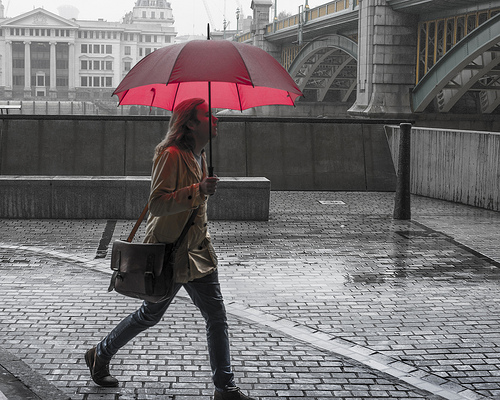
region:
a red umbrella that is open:
[121, 25, 296, 103]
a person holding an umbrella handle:
[195, 78, 220, 195]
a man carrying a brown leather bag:
[105, 100, 241, 300]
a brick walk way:
[307, 244, 426, 316]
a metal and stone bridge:
[220, 10, 498, 105]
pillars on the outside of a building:
[17, 40, 59, 95]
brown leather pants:
[75, 275, 251, 369]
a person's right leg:
[105, 295, 166, 341]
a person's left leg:
[194, 288, 245, 375]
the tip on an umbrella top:
[202, 20, 217, 44]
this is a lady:
[135, 95, 239, 349]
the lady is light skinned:
[199, 117, 204, 142]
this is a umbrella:
[146, 38, 273, 93]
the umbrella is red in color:
[205, 57, 246, 79]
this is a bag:
[83, 232, 171, 304]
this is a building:
[21, 20, 111, 84]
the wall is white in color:
[64, 51, 84, 85]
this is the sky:
[90, 1, 118, 17]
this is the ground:
[291, 287, 448, 368]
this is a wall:
[273, 133, 354, 171]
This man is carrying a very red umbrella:
[161, 59, 269, 106]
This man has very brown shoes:
[207, 368, 237, 389]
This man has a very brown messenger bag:
[111, 221, 185, 301]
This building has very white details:
[78, 58, 92, 83]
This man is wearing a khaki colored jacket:
[167, 170, 214, 232]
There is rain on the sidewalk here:
[419, 227, 456, 305]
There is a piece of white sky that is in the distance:
[187, 10, 192, 29]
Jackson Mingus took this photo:
[68, 40, 408, 397]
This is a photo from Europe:
[105, 58, 485, 383]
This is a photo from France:
[101, 46, 328, 397]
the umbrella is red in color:
[203, 44, 230, 79]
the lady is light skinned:
[192, 120, 216, 155]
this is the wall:
[76, 32, 93, 86]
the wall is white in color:
[107, 40, 128, 64]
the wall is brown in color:
[281, 17, 300, 23]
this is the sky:
[181, 5, 211, 27]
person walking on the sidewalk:
[42, 44, 329, 398]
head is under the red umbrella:
[101, 37, 314, 172]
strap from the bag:
[122, 198, 154, 240]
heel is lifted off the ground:
[80, 347, 101, 377]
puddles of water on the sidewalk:
[196, 208, 493, 310]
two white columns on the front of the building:
[18, 39, 68, 94]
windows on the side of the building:
[77, 40, 119, 89]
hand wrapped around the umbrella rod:
[199, 164, 224, 197]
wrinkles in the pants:
[204, 275, 230, 304]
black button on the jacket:
[199, 218, 211, 235]